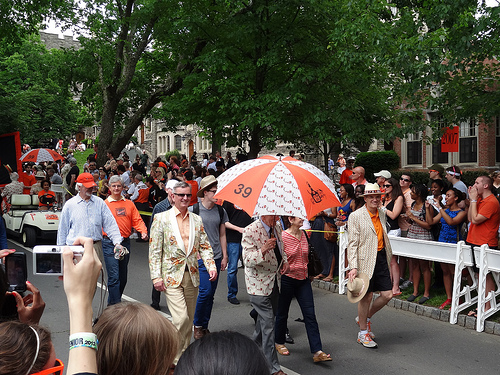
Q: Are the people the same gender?
A: No, they are both male and female.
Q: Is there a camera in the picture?
A: Yes, there is a camera.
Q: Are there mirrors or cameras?
A: Yes, there is a camera.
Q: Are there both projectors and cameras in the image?
A: No, there is a camera but no projectors.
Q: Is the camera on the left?
A: Yes, the camera is on the left of the image.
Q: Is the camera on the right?
A: No, the camera is on the left of the image.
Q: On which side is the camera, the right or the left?
A: The camera is on the left of the image.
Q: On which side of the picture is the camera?
A: The camera is on the left of the image.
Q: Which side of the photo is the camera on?
A: The camera is on the left of the image.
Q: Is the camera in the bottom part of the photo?
A: Yes, the camera is in the bottom of the image.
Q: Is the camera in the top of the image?
A: No, the camera is in the bottom of the image.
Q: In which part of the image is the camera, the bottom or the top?
A: The camera is in the bottom of the image.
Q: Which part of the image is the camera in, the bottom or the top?
A: The camera is in the bottom of the image.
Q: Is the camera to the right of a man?
A: No, the camera is to the left of a man.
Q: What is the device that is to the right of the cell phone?
A: The device is a camera.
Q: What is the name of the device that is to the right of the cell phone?
A: The device is a camera.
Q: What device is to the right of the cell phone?
A: The device is a camera.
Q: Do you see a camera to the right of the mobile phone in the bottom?
A: Yes, there is a camera to the right of the cellphone.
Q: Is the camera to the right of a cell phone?
A: Yes, the camera is to the right of a cell phone.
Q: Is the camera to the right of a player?
A: No, the camera is to the right of a cell phone.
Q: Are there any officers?
A: No, there are no officers.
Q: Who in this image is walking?
A: The man is walking.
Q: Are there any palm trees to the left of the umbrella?
A: No, there is a man to the left of the umbrella.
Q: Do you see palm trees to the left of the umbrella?
A: No, there is a man to the left of the umbrella.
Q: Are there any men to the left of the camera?
A: No, the man is to the right of the camera.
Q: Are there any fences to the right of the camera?
A: No, there is a man to the right of the camera.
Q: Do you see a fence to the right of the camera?
A: No, there is a man to the right of the camera.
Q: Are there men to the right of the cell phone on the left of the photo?
A: Yes, there is a man to the right of the cellphone.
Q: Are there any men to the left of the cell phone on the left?
A: No, the man is to the right of the mobile phone.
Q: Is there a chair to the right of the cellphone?
A: No, there is a man to the right of the cellphone.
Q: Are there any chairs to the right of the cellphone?
A: No, there is a man to the right of the cellphone.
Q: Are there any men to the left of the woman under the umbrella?
A: Yes, there is a man to the left of the woman.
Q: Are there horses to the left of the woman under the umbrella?
A: No, there is a man to the left of the woman.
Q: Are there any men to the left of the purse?
A: Yes, there is a man to the left of the purse.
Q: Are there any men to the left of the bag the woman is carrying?
A: Yes, there is a man to the left of the purse.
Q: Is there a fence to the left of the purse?
A: No, there is a man to the left of the purse.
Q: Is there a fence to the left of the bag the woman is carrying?
A: No, there is a man to the left of the purse.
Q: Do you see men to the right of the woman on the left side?
A: Yes, there is a man to the right of the woman.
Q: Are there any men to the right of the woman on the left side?
A: Yes, there is a man to the right of the woman.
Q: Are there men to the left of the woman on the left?
A: No, the man is to the right of the woman.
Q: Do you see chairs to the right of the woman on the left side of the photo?
A: No, there is a man to the right of the woman.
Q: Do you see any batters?
A: No, there are no batters.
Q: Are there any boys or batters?
A: No, there are no batters or boys.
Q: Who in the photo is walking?
A: The man is walking.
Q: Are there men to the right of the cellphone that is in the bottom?
A: Yes, there is a man to the right of the mobile phone.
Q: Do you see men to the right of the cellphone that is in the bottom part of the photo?
A: Yes, there is a man to the right of the mobile phone.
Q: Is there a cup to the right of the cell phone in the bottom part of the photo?
A: No, there is a man to the right of the mobile phone.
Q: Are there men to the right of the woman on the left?
A: Yes, there is a man to the right of the woman.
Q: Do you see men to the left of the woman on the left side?
A: No, the man is to the right of the woman.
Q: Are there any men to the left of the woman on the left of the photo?
A: No, the man is to the right of the woman.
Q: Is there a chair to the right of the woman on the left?
A: No, there is a man to the right of the woman.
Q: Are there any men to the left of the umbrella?
A: Yes, there is a man to the left of the umbrella.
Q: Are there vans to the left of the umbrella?
A: No, there is a man to the left of the umbrella.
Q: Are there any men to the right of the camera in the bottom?
A: Yes, there is a man to the right of the camera.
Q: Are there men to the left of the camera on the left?
A: No, the man is to the right of the camera.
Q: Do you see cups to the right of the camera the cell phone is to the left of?
A: No, there is a man to the right of the camera.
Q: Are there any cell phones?
A: Yes, there is a cell phone.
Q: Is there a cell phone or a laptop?
A: Yes, there is a cell phone.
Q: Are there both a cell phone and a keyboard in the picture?
A: No, there is a cell phone but no keyboards.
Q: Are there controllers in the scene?
A: No, there are no controllers.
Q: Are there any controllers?
A: No, there are no controllers.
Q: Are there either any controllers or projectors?
A: No, there are no controllers or projectors.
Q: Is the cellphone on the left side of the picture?
A: Yes, the cellphone is on the left of the image.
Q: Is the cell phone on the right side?
A: No, the cell phone is on the left of the image.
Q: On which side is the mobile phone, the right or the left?
A: The mobile phone is on the left of the image.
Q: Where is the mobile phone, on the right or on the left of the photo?
A: The mobile phone is on the left of the image.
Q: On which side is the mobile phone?
A: The mobile phone is on the left of the image.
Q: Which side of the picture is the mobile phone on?
A: The mobile phone is on the left of the image.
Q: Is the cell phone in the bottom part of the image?
A: Yes, the cell phone is in the bottom of the image.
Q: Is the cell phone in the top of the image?
A: No, the cell phone is in the bottom of the image.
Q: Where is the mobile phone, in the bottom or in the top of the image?
A: The mobile phone is in the bottom of the image.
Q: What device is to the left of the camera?
A: The device is a cell phone.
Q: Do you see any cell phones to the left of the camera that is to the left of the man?
A: Yes, there is a cell phone to the left of the camera.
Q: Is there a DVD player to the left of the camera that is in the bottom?
A: No, there is a cell phone to the left of the camera.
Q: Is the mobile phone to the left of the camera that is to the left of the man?
A: Yes, the mobile phone is to the left of the camera.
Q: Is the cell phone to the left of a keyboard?
A: No, the cell phone is to the left of the camera.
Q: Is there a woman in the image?
A: Yes, there is a woman.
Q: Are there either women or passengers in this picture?
A: Yes, there is a woman.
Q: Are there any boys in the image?
A: No, there are no boys.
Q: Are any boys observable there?
A: No, there are no boys.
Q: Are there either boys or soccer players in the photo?
A: No, there are no boys or soccer players.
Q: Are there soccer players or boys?
A: No, there are no boys or soccer players.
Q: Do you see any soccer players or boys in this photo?
A: No, there are no boys or soccer players.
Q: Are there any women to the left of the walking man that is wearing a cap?
A: Yes, there is a woman to the left of the man.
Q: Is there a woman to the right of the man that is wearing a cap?
A: No, the woman is to the left of the man.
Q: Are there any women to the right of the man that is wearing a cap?
A: No, the woman is to the left of the man.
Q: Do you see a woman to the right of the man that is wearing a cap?
A: No, the woman is to the left of the man.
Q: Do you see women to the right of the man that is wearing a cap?
A: No, the woman is to the left of the man.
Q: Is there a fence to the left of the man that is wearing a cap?
A: No, there is a woman to the left of the man.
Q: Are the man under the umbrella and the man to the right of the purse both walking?
A: Yes, both the man and the man are walking.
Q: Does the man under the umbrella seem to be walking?
A: Yes, the man is walking.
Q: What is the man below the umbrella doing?
A: The man is walking.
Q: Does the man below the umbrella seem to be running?
A: No, the man is walking.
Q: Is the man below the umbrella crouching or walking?
A: The man is walking.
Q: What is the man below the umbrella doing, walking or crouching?
A: The man is walking.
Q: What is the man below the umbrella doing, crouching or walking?
A: The man is walking.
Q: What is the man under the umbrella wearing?
A: The man is wearing a blazer.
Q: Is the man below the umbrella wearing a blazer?
A: Yes, the man is wearing a blazer.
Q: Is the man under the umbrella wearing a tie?
A: No, the man is wearing a blazer.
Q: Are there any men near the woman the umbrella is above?
A: Yes, there is a man near the woman.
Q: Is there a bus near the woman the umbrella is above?
A: No, there is a man near the woman.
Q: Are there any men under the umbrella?
A: Yes, there is a man under the umbrella.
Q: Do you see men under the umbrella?
A: Yes, there is a man under the umbrella.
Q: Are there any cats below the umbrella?
A: No, there is a man below the umbrella.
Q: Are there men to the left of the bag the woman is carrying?
A: Yes, there is a man to the left of the purse.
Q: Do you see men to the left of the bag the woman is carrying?
A: Yes, there is a man to the left of the purse.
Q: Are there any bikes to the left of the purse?
A: No, there is a man to the left of the purse.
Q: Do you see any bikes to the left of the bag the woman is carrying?
A: No, there is a man to the left of the purse.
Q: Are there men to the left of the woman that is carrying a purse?
A: Yes, there is a man to the left of the woman.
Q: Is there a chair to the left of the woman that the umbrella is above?
A: No, there is a man to the left of the woman.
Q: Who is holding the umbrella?
A: The man is holding the umbrella.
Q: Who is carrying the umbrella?
A: The man is carrying the umbrella.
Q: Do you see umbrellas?
A: Yes, there is an umbrella.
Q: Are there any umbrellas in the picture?
A: Yes, there is an umbrella.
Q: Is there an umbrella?
A: Yes, there is an umbrella.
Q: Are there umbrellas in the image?
A: Yes, there is an umbrella.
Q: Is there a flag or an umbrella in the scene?
A: Yes, there is an umbrella.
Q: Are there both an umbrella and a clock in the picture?
A: No, there is an umbrella but no clocks.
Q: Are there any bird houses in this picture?
A: No, there are no bird houses.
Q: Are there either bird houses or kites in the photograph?
A: No, there are no bird houses or kites.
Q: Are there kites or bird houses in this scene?
A: No, there are no bird houses or kites.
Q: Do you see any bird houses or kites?
A: No, there are no bird houses or kites.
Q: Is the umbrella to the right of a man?
A: Yes, the umbrella is to the right of a man.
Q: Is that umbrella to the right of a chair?
A: No, the umbrella is to the right of a man.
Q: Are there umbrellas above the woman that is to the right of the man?
A: Yes, there is an umbrella above the woman.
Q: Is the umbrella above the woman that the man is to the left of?
A: Yes, the umbrella is above the woman.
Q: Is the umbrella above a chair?
A: No, the umbrella is above the woman.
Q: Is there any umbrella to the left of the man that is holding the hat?
A: Yes, there is an umbrella to the left of the man.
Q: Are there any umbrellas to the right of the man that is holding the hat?
A: No, the umbrella is to the left of the man.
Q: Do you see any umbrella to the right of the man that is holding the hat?
A: No, the umbrella is to the left of the man.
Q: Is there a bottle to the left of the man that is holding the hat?
A: No, there is an umbrella to the left of the man.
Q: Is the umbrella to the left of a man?
A: Yes, the umbrella is to the left of a man.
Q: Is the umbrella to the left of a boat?
A: No, the umbrella is to the left of a man.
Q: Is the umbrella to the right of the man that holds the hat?
A: No, the umbrella is to the left of the man.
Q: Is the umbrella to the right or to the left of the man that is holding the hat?
A: The umbrella is to the left of the man.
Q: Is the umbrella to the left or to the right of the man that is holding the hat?
A: The umbrella is to the left of the man.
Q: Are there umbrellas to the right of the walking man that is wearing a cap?
A: Yes, there is an umbrella to the right of the man.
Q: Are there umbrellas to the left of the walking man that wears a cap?
A: No, the umbrella is to the right of the man.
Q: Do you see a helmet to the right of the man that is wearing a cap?
A: No, there is an umbrella to the right of the man.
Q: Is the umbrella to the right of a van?
A: No, the umbrella is to the right of the man.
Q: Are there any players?
A: No, there are no players.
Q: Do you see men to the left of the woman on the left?
A: No, the man is to the right of the woman.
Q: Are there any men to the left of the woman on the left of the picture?
A: No, the man is to the right of the woman.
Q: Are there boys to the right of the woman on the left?
A: No, there is a man to the right of the woman.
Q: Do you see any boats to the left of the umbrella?
A: No, there is a man to the left of the umbrella.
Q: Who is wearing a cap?
A: The man is wearing a cap.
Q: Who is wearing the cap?
A: The man is wearing a cap.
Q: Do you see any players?
A: No, there are no players.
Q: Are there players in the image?
A: No, there are no players.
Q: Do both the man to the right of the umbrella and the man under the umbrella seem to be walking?
A: Yes, both the man and the man are walking.